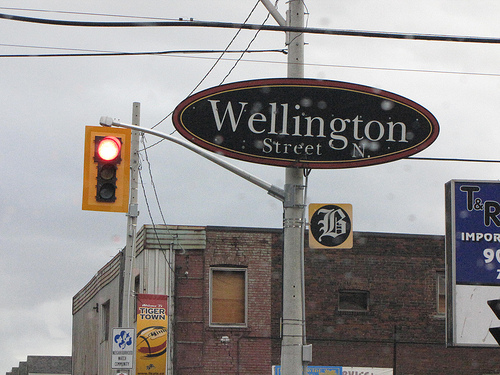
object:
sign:
[166, 73, 437, 172]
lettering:
[204, 94, 409, 145]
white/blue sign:
[109, 324, 138, 370]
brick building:
[61, 217, 500, 375]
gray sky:
[0, 0, 500, 375]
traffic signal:
[79, 117, 135, 215]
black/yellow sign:
[306, 199, 356, 251]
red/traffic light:
[95, 134, 126, 163]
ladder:
[168, 246, 210, 372]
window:
[206, 265, 251, 328]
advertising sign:
[439, 172, 500, 351]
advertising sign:
[127, 288, 178, 375]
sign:
[108, 324, 138, 372]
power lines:
[0, 10, 500, 47]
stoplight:
[77, 121, 136, 218]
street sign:
[105, 350, 141, 374]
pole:
[274, 0, 313, 374]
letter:
[385, 120, 410, 145]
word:
[203, 96, 413, 144]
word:
[260, 136, 328, 161]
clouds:
[0, 0, 500, 234]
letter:
[206, 95, 246, 135]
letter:
[459, 185, 481, 212]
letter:
[327, 115, 352, 152]